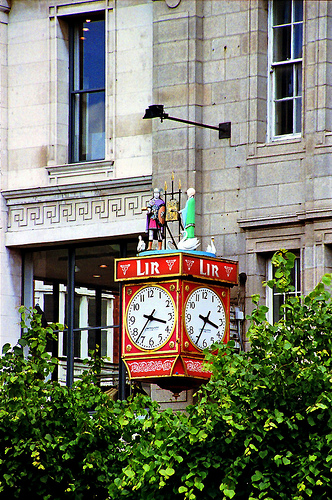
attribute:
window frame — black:
[17, 242, 131, 404]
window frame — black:
[67, 16, 109, 160]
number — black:
[128, 315, 136, 326]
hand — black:
[143, 313, 167, 324]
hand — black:
[134, 308, 153, 343]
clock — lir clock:
[120, 280, 175, 357]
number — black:
[202, 291, 209, 300]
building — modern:
[0, 0, 331, 411]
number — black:
[201, 291, 209, 300]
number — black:
[188, 325, 194, 333]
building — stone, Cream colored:
[0, 0, 148, 235]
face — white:
[112, 244, 238, 386]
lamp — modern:
[139, 100, 240, 142]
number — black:
[131, 301, 140, 311]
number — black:
[165, 310, 174, 320]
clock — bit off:
[105, 242, 246, 409]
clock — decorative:
[112, 170, 239, 398]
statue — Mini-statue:
[176, 187, 198, 251]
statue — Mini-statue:
[147, 187, 167, 250]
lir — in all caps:
[135, 257, 159, 277]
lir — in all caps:
[198, 258, 220, 277]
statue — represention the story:
[149, 188, 168, 248]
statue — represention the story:
[177, 185, 200, 252]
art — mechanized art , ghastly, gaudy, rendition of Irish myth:
[135, 190, 218, 254]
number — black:
[143, 288, 153, 298]